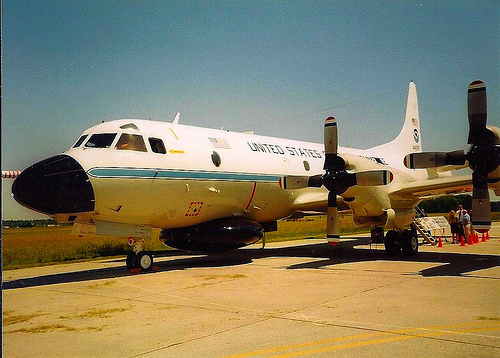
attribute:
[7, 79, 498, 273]
airplane — in the picture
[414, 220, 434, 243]
bridge — in the picture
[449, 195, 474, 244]
people — in the picture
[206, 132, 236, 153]
american flag — in the picture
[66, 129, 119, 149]
window — in the picture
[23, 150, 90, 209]
nose — black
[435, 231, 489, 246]
cones — in the picture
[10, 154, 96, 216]
nose — black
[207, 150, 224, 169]
windows — small, round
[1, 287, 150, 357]
stains — in the picture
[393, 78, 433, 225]
tail — in the picture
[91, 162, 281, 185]
stripe — in the picture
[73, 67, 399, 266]
plane — in the picture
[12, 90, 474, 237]
airplane — in the picture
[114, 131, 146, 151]
window — small, paned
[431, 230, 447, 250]
cone — orange 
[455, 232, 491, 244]
traffic cones — in the picture